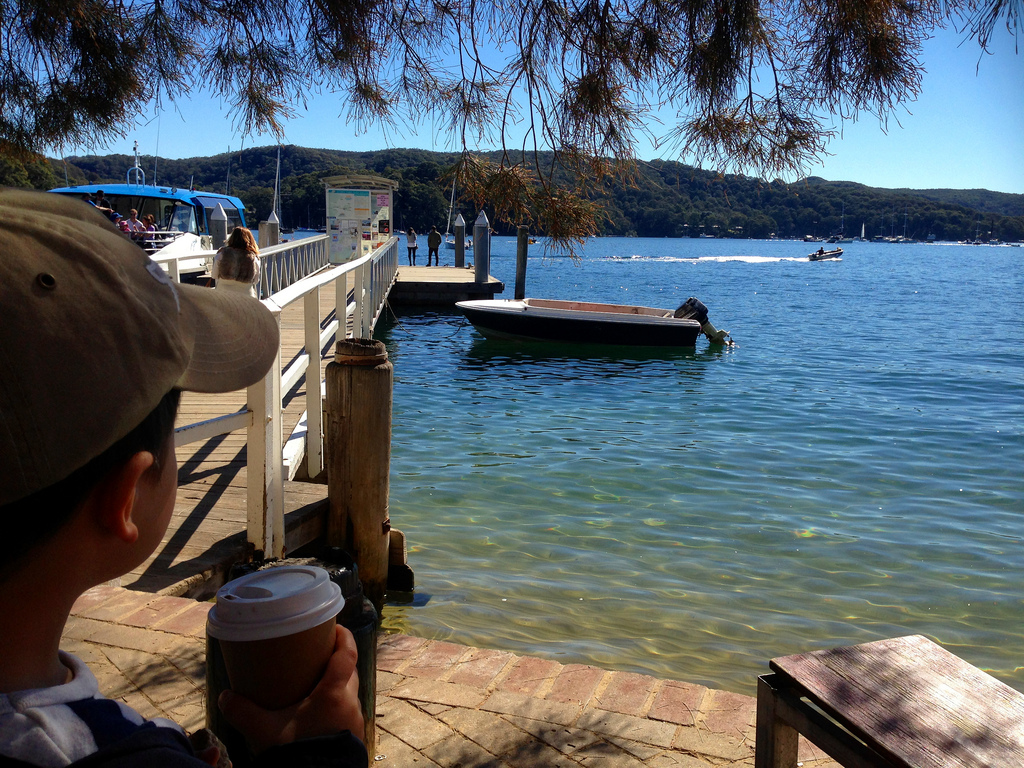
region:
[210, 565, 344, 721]
The cup held by the boy with the tan hat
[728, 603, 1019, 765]
The wood bench near the water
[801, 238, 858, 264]
The boat moving in the water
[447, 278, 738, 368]
The boat with no one in it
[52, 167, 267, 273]
The boat with the blue cover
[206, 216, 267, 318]
The woman with red hair standing on the dock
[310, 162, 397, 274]
The information board at the end of the dock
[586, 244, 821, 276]
The wake behind the moving boat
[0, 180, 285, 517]
The tan hat worn by the boy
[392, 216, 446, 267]
The two people standing at the end of the dock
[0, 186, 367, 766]
boy wearing a tan hat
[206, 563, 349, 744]
white lid on paper cup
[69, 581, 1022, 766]
wooden bench on brick walkway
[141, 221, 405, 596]
woman walking on wooden dock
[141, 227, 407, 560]
white railing on dock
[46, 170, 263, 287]
people on blue and white boat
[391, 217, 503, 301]
people standing on wooden dock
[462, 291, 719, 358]
a small white speedboat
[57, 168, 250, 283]
a large blue and white boat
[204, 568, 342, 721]
a brown and white coffee cup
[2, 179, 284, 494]
a brown baseball cap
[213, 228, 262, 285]
a woman's long brown hair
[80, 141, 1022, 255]
a long mountain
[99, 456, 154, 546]
the ear of a boy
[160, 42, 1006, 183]
a blue sky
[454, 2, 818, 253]
brown tree leaves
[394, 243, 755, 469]
boat in the water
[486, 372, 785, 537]
water next to boat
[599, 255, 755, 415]
back of the boat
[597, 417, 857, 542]
ripples in the water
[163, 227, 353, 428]
brim of the hat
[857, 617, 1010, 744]
light hitting the board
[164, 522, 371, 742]
drink in person's hand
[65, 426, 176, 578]
ear of the person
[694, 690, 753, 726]
red brick paver on the dock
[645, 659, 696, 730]
red brick paver on the dock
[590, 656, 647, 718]
red brick paver on the dock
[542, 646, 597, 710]
red brick paver on the dock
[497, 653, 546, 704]
red brick paver on the dock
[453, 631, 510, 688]
red brick paver on the dock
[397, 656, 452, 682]
red brick paver on the dock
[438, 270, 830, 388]
boat in water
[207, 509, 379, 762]
boy holding coffe cup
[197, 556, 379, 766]
carry out cup with white in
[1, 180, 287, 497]
tan baseball hat on person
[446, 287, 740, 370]
small white and dark boat with motor on back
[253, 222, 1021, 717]
small body of water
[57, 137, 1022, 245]
line of green foliage bordering water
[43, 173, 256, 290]
white boat with blue tarp top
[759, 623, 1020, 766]
plank of wood on top of table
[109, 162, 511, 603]
long wooden ramp in front of water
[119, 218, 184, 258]
metal fence on back of boat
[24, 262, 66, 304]
metal hole on top of baseball cap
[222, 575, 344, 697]
cup of coffee held by man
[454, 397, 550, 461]
ripples in dark blue water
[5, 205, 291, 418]
brown cap worn by boy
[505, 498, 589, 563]
ripples in dark blue water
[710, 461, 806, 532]
ripples in dark blue water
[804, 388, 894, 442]
ripples in dark blue water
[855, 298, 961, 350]
ripples in dark blue water